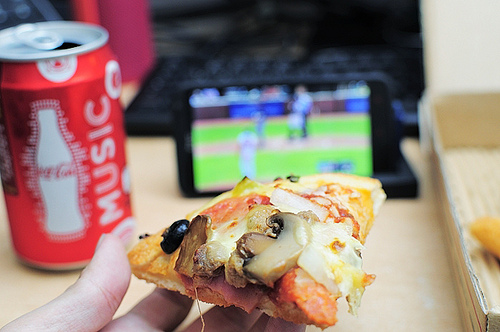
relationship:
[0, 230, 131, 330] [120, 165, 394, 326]
finger touching pizza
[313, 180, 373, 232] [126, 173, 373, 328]
cheese on pizza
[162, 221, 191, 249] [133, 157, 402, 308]
olive on top of pizza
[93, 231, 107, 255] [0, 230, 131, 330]
fingernail on finger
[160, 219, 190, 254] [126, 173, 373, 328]
olive are on pizza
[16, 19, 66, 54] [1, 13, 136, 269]
tab on top of can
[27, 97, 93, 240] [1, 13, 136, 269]
bottle printed on can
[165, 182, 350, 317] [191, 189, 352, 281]
vegetables on pizza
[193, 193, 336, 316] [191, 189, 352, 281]
meat on pizza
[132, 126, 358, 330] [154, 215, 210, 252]
pizza with black olives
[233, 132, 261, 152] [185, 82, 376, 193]
part of a screen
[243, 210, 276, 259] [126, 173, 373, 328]
part of a pizza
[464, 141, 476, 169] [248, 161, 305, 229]
part of a plate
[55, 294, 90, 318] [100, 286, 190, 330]
part of a finger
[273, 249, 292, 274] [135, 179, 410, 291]
part of a pizza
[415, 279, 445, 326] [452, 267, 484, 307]
part of a table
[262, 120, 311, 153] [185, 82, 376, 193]
part of a screen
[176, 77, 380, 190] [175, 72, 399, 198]
baseball game being watched on a cell phone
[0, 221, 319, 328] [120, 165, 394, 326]
hand holding pizza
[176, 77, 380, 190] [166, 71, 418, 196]
baseball game on a cell phone